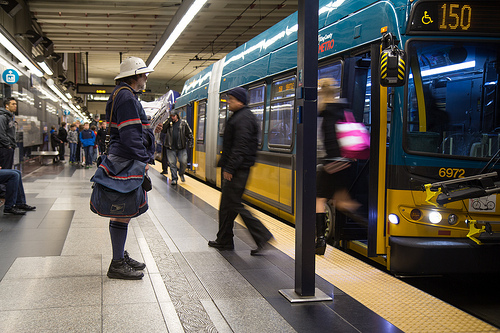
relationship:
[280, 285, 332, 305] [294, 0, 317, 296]
base holding beam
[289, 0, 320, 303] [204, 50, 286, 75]
beam supporting roof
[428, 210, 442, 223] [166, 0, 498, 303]
shining light on train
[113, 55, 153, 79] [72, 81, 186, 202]
hard hat on man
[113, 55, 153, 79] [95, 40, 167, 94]
hard hat on head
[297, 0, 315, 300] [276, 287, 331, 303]
pillar on base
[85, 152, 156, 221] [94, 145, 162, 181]
bag at waist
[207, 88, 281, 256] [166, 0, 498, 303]
man walking out of train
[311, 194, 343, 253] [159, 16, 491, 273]
wheel on front of bus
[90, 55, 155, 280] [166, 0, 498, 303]
mail man waiting for train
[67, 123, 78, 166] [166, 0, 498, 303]
child waiting for train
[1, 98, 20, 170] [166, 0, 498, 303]
man waiting for train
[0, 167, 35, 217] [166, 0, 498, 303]
person waiting for train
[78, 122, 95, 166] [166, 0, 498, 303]
child waiting for train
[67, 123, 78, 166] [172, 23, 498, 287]
child waiting for train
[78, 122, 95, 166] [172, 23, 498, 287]
child waiting for train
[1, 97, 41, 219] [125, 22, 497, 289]
man waiting for train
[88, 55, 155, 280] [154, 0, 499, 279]
mail man waiting for train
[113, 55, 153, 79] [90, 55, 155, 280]
hard hat on mail man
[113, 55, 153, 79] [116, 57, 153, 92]
hard hat on head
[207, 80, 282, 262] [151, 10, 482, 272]
man getting off train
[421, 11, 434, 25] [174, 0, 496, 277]
handicap sign on bus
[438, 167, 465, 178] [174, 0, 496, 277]
6972 on bus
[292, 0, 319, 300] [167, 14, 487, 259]
pillar near train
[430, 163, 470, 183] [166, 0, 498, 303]
numbers on front of train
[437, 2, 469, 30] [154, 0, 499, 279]
numbers 150 on front of train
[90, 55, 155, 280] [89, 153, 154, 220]
mail man carrying bag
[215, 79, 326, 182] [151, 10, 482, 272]
windows on side of train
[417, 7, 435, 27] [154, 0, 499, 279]
handicap sign on front of train